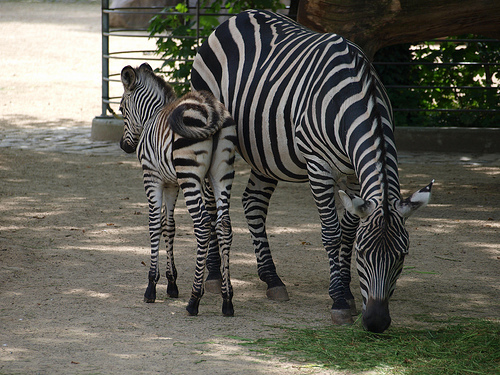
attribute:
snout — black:
[120, 136, 137, 153]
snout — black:
[364, 299, 392, 333]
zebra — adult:
[227, 8, 415, 310]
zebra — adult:
[172, 3, 438, 346]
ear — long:
[396, 169, 441, 223]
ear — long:
[332, 180, 373, 212]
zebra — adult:
[190, 5, 434, 334]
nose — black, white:
[362, 294, 392, 336]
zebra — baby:
[104, 62, 232, 324]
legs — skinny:
[135, 174, 180, 300]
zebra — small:
[97, 59, 242, 338]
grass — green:
[255, 319, 499, 374]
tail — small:
[161, 94, 232, 154]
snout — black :
[117, 132, 133, 154]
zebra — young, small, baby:
[117, 59, 238, 319]